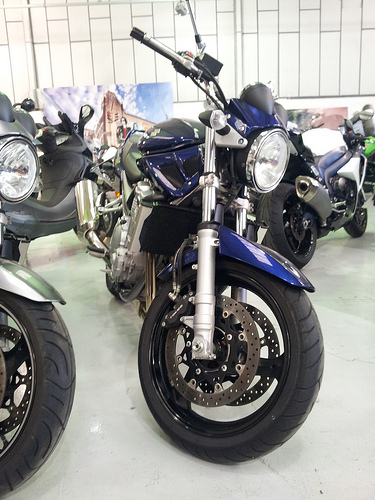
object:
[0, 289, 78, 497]
front tire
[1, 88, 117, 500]
motorcycle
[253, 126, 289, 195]
headlights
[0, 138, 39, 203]
headlights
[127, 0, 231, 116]
handle bar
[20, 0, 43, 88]
bar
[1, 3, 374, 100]
window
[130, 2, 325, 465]
front end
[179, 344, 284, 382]
spokes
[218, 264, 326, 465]
part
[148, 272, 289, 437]
rim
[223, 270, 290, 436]
part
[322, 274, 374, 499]
part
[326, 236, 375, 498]
floor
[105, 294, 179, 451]
shadow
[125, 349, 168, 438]
part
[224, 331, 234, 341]
bolt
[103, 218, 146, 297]
engine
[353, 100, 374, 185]
bikes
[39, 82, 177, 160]
painting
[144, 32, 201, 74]
break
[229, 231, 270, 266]
reflection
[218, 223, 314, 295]
fender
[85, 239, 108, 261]
treads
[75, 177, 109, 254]
pipe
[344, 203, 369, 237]
back tire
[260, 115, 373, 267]
motorcycle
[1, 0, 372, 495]
garage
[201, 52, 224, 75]
dial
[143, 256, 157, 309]
shock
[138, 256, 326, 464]
tire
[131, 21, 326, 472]
front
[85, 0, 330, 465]
motorcycle